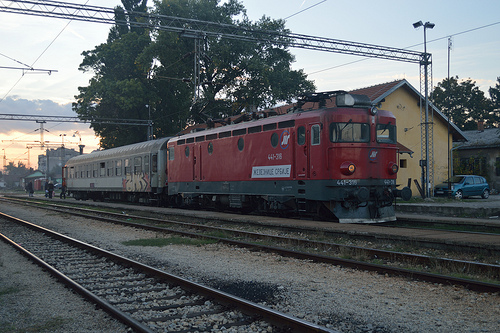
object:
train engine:
[166, 104, 397, 223]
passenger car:
[65, 137, 166, 206]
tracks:
[382, 218, 497, 237]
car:
[433, 174, 488, 200]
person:
[58, 182, 68, 200]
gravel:
[114, 293, 197, 306]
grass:
[122, 237, 216, 246]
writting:
[250, 164, 290, 176]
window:
[330, 120, 370, 143]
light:
[341, 161, 355, 174]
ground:
[1, 192, 498, 330]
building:
[362, 77, 467, 201]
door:
[293, 116, 323, 180]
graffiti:
[121, 172, 152, 193]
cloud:
[0, 96, 96, 133]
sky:
[0, 1, 499, 93]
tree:
[73, 1, 316, 147]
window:
[376, 123, 398, 142]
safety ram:
[392, 185, 412, 201]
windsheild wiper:
[337, 119, 353, 132]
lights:
[412, 20, 435, 30]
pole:
[423, 24, 429, 198]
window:
[398, 158, 406, 170]